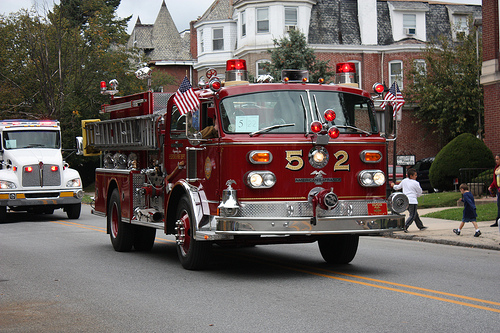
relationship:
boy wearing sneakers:
[451, 174, 492, 243] [453, 228, 479, 238]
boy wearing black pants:
[399, 173, 425, 233] [406, 203, 426, 230]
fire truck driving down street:
[75, 59, 410, 270] [13, 210, 426, 328]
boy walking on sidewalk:
[453, 183, 482, 237] [412, 220, 496, 247]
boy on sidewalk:
[391, 168, 428, 233] [392, 217, 495, 246]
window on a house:
[378, 59, 420, 113] [193, 1, 476, 188]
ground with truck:
[0, 205, 500, 333] [86, 69, 415, 276]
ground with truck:
[0, 205, 500, 333] [0, 109, 85, 226]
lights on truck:
[242, 165, 385, 192] [67, 40, 419, 275]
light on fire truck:
[244, 149, 278, 162] [77, 46, 402, 255]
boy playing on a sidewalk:
[453, 183, 482, 237] [388, 194, 493, 255]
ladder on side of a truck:
[82, 116, 159, 153] [81, 84, 413, 267]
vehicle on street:
[1, 116, 88, 219] [4, 198, 489, 330]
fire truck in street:
[75, 59, 410, 270] [2, 220, 499, 331]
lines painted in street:
[297, 260, 499, 312] [8, 237, 498, 331]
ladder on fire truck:
[76, 113, 162, 156] [102, 85, 407, 270]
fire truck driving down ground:
[68, 71, 404, 278] [0, 205, 500, 333]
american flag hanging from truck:
[171, 75, 200, 116] [81, 84, 413, 267]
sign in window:
[233, 110, 263, 135] [217, 87, 317, 134]